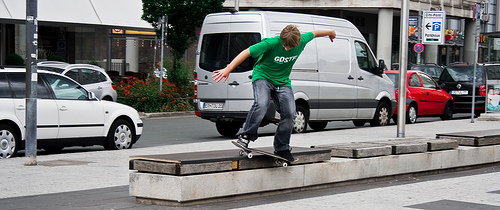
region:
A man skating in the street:
[240, 14, 316, 160]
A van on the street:
[195, 11, 397, 123]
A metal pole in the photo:
[17, 27, 40, 154]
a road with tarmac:
[159, 110, 219, 142]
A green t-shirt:
[247, 37, 309, 82]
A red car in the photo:
[392, 62, 458, 123]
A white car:
[0, 55, 150, 156]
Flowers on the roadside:
[112, 74, 190, 106]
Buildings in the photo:
[428, 9, 483, 59]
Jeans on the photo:
[241, 78, 299, 149]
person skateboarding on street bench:
[205, 20, 345, 167]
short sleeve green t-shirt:
[244, 30, 314, 86]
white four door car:
[0, 59, 147, 159]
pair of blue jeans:
[237, 73, 298, 153]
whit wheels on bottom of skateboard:
[236, 148, 292, 175]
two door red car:
[380, 60, 456, 124]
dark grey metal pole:
[21, 0, 44, 163]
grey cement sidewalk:
[2, 117, 499, 206]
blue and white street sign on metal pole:
[394, 2, 449, 139]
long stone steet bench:
[125, 121, 496, 207]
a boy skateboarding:
[99, 8, 497, 175]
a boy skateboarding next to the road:
[164, 23, 433, 195]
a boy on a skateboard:
[171, 16, 368, 158]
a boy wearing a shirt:
[186, 1, 368, 204]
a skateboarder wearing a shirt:
[186, 8, 315, 175]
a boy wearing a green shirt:
[205, 18, 408, 208]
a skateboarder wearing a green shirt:
[185, 11, 351, 181]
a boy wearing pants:
[202, 18, 346, 182]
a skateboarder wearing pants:
[214, 16, 341, 194]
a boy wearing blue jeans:
[222, 19, 335, 179]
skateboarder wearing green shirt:
[219, 26, 347, 163]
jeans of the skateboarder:
[236, 84, 302, 150]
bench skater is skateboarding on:
[123, 146, 328, 188]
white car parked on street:
[2, 62, 142, 151]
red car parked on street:
[395, 55, 449, 116]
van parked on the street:
[202, 16, 397, 128]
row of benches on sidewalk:
[133, 125, 498, 209]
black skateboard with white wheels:
[234, 140, 292, 174]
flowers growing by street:
[118, 65, 183, 106]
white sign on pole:
[416, 12, 444, 46]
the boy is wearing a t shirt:
[248, 25, 313, 90]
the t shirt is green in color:
[250, 26, 314, 92]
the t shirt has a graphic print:
[276, 51, 301, 64]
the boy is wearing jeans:
[243, 80, 296, 149]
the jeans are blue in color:
[242, 78, 300, 148]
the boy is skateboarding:
[216, 20, 331, 165]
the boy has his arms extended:
[208, 21, 338, 75]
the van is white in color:
[202, 7, 397, 129]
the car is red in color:
[379, 68, 456, 122]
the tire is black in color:
[375, 99, 392, 125]